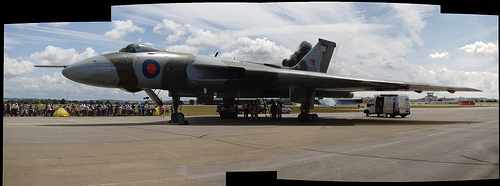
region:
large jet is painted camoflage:
[51, 30, 474, 127]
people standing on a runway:
[5, 94, 161, 119]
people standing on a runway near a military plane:
[1, 35, 471, 128]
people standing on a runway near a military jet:
[4, 42, 411, 132]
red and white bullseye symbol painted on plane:
[140, 55, 160, 77]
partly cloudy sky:
[330, 10, 495, 80]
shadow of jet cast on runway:
[155, 115, 481, 130]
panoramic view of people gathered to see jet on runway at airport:
[1, 5, 497, 175]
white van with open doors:
[365, 90, 410, 118]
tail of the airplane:
[292, 37, 334, 74]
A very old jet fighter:
[67, 32, 489, 127]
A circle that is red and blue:
[132, 53, 164, 81]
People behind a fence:
[0, 98, 166, 123]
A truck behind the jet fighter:
[364, 92, 426, 139]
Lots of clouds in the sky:
[360, 11, 471, 78]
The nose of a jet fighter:
[56, 44, 149, 89]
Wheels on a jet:
[166, 112, 196, 132]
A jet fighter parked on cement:
[87, 56, 445, 146]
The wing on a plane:
[210, 53, 496, 96]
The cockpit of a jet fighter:
[112, 40, 154, 58]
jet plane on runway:
[30, 35, 480, 125]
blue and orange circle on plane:
[139, 56, 161, 81]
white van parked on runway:
[364, 90, 409, 118]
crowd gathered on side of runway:
[5, 98, 160, 120]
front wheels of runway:
[170, 110, 185, 122]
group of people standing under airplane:
[238, 97, 283, 119]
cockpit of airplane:
[119, 40, 158, 51]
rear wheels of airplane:
[294, 108, 319, 126]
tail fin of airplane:
[290, 38, 339, 73]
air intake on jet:
[187, 60, 249, 85]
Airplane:
[34, 38, 482, 126]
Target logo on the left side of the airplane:
[142, 55, 162, 80]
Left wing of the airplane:
[191, 60, 480, 92]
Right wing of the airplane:
[30, 62, 67, 68]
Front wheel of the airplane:
[165, 94, 188, 123]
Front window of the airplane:
[118, 42, 163, 51]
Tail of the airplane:
[290, 35, 357, 73]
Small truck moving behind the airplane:
[362, 95, 414, 120]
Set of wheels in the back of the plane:
[296, 102, 321, 124]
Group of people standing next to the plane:
[3, 97, 183, 119]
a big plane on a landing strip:
[30, 33, 488, 125]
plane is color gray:
[34, 30, 485, 122]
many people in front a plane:
[5, 92, 165, 122]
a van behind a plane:
[353, 88, 417, 123]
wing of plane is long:
[191, 56, 488, 100]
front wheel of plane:
[167, 98, 188, 125]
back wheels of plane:
[289, 103, 322, 124]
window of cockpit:
[119, 36, 164, 56]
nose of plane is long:
[54, 53, 111, 90]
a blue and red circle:
[139, 54, 165, 83]